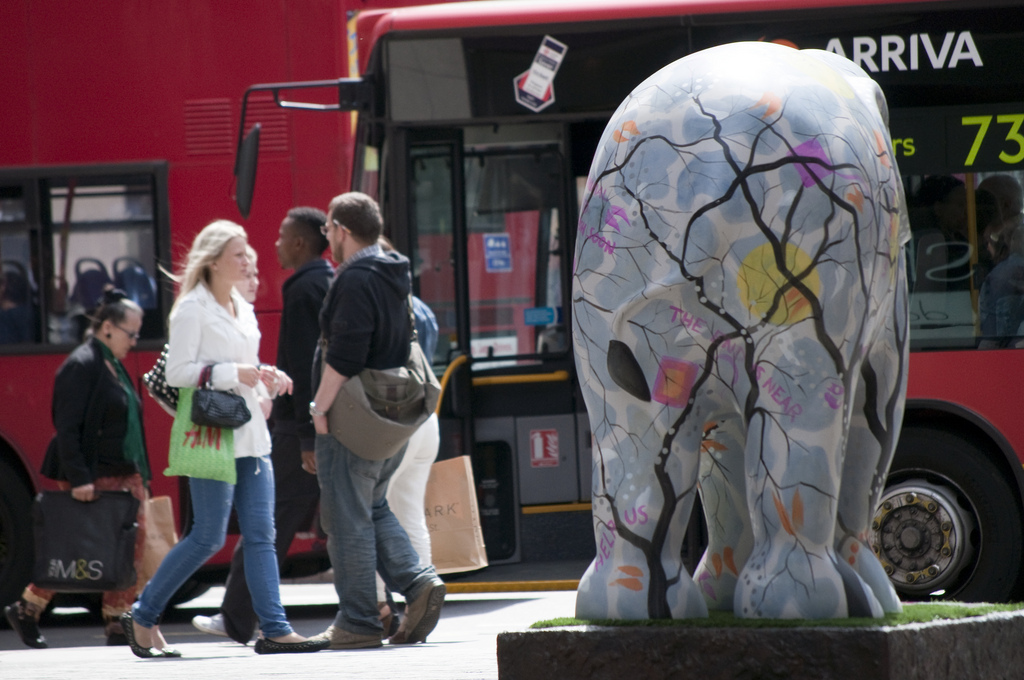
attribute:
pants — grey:
[331, 384, 409, 601]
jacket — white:
[167, 282, 271, 458]